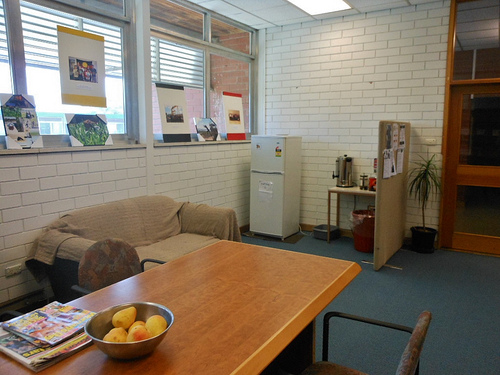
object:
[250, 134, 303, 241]
refrigerator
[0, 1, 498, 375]
brake room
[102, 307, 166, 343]
pears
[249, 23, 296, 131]
corner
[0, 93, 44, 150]
photo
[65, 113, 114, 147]
photo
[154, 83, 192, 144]
photo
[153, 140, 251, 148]
ledge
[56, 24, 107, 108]
picture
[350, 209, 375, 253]
trash bag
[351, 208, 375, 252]
can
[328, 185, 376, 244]
table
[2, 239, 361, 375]
table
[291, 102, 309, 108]
brick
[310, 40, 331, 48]
brick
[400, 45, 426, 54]
brick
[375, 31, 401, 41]
brick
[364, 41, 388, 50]
brick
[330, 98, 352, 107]
white brick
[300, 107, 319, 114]
white brick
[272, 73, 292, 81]
white brick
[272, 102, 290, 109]
white brick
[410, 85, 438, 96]
white brick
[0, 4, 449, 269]
building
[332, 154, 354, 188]
coffe pot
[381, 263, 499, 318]
ground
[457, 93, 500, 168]
pane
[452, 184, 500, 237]
pane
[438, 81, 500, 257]
door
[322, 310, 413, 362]
armrest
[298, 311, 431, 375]
chair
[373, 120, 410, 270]
partition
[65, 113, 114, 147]
icture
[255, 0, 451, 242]
brick wall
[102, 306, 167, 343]
fruit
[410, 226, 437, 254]
black pot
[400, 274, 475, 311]
carpet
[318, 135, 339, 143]
bricks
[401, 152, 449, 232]
plant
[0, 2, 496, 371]
room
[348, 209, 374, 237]
bag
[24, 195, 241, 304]
seat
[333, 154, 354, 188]
container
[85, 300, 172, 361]
bowl/table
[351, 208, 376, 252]
pail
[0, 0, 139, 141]
blinds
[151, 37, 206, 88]
blinds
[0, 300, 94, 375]
papers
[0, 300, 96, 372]
magazines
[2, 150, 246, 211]
wall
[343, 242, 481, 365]
floor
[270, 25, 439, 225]
wall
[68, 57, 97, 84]
artwork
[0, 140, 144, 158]
window sill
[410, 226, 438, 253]
pot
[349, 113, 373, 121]
bricks